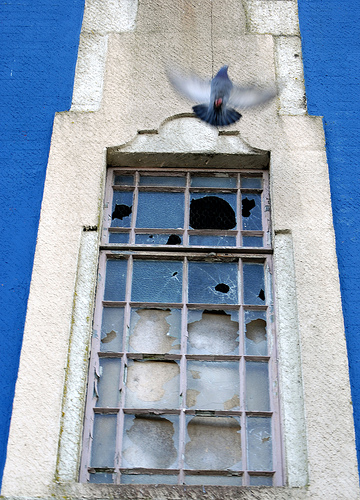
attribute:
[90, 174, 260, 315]
window — broken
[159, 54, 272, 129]
bird — flying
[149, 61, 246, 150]
bird — flying